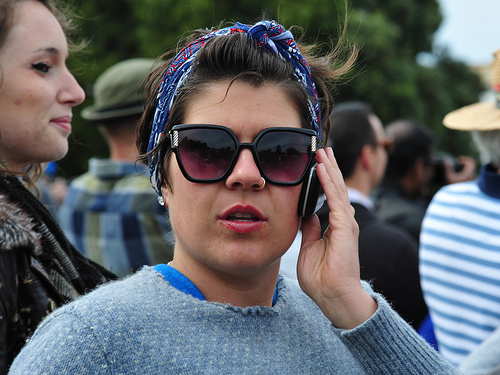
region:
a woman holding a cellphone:
[9, 24, 456, 373]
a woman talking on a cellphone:
[9, 34, 437, 374]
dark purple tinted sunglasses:
[161, 124, 319, 182]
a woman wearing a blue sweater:
[11, 35, 463, 374]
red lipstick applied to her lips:
[212, 204, 268, 232]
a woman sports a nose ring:
[10, 27, 452, 372]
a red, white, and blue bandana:
[142, 20, 324, 200]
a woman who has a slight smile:
[1, 0, 85, 182]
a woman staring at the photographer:
[8, 26, 454, 373]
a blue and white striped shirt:
[420, 177, 499, 363]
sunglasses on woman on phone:
[162, 114, 336, 194]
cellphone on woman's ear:
[287, 145, 357, 220]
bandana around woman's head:
[115, 17, 327, 132]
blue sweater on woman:
[53, 280, 355, 364]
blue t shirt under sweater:
[157, 257, 218, 311]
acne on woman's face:
[5, 77, 27, 114]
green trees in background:
[49, 24, 445, 85]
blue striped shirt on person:
[424, 191, 494, 291]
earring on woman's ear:
[159, 186, 169, 216]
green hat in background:
[79, 53, 165, 119]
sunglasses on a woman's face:
[162, 125, 322, 190]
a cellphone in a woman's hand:
[296, 151, 328, 223]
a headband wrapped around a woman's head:
[144, 20, 327, 196]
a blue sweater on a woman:
[5, 264, 461, 374]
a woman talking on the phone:
[9, 22, 455, 372]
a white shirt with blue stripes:
[418, 180, 498, 374]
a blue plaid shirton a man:
[54, 161, 184, 283]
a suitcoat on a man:
[316, 196, 426, 337]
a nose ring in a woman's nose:
[256, 176, 266, 192]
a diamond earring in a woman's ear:
[152, 193, 172, 208]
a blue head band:
[149, 21, 319, 177]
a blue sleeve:
[346, 305, 447, 373]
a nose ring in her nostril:
[255, 175, 267, 191]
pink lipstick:
[215, 203, 271, 230]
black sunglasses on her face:
[160, 119, 320, 187]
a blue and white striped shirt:
[419, 181, 498, 359]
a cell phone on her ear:
[297, 155, 335, 220]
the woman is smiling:
[3, 3, 86, 165]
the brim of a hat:
[441, 87, 499, 132]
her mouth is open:
[211, 204, 278, 241]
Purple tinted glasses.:
[161, 120, 321, 190]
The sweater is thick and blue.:
[108, 300, 187, 354]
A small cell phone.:
[300, 162, 322, 220]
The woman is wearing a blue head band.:
[143, 15, 330, 135]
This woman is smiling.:
[3, 0, 91, 190]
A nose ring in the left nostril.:
[253, 173, 265, 196]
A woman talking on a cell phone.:
[27, 6, 466, 373]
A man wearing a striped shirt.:
[400, 177, 498, 362]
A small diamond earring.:
[153, 197, 167, 207]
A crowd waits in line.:
[89, 58, 471, 305]